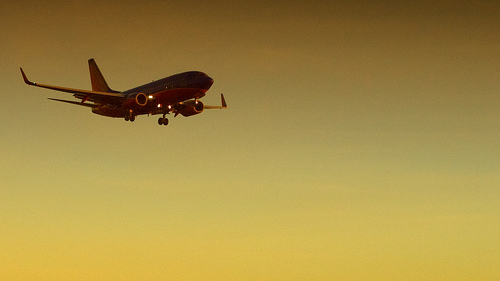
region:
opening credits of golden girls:
[13, 15, 326, 227]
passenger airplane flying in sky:
[18, 32, 318, 227]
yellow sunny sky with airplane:
[17, 39, 377, 219]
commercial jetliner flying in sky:
[11, 27, 273, 173]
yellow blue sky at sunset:
[246, 47, 455, 247]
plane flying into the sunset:
[13, 23, 399, 264]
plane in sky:
[11, 25, 284, 187]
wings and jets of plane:
[13, 35, 250, 177]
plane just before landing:
[8, 17, 350, 208]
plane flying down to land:
[12, 32, 317, 172]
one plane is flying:
[18, 52, 245, 125]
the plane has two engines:
[115, 77, 270, 140]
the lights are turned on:
[117, 87, 264, 127]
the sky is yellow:
[234, 66, 377, 255]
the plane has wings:
[6, 62, 281, 154]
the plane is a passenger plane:
[58, 35, 335, 194]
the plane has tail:
[65, 39, 222, 135]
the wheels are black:
[89, 107, 219, 145]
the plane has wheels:
[97, 107, 230, 148]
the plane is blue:
[15, 42, 310, 149]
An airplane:
[22, 53, 246, 129]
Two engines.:
[122, 91, 206, 121]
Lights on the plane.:
[146, 93, 181, 114]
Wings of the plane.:
[19, 68, 253, 114]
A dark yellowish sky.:
[244, 4, 473, 277]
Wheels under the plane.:
[153, 114, 174, 126]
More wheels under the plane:
[117, 112, 138, 125]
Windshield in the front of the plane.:
[190, 67, 215, 88]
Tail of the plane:
[57, 56, 127, 125]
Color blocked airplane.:
[65, 62, 240, 132]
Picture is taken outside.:
[14, 10, 489, 270]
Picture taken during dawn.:
[22, 17, 408, 243]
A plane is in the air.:
[14, 19, 411, 260]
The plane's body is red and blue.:
[15, 55, 256, 140]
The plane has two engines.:
[94, 91, 218, 133]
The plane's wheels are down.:
[118, 105, 175, 130]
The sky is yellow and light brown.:
[259, 45, 396, 272]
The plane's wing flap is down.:
[62, 84, 120, 118]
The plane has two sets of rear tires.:
[114, 108, 181, 150]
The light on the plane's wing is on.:
[22, 65, 42, 92]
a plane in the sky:
[19, 50, 226, 135]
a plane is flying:
[13, 47, 228, 133]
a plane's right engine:
[119, 90, 148, 112]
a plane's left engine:
[175, 97, 202, 122]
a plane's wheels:
[156, 115, 171, 130]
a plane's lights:
[153, 102, 168, 107]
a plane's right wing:
[8, 66, 119, 108]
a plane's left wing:
[200, 92, 230, 113]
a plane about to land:
[11, 51, 224, 138]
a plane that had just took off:
[14, 38, 266, 138]